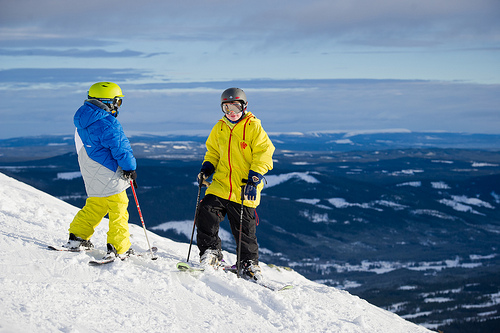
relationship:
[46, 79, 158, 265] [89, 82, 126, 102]
skiers wearing helmet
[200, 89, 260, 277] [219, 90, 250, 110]
person wearing helmet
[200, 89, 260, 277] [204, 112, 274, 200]
person wearing jacket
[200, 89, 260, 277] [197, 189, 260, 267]
person wearing pants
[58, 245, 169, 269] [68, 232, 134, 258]
skis attached to feet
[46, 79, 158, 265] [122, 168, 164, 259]
skiers holding pole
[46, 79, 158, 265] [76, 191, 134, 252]
skiers wearing pants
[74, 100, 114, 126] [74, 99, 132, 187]
hood on back of jacket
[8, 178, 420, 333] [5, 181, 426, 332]
snow on top of ground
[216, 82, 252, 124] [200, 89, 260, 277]
head of person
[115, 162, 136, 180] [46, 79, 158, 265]
hand of skiers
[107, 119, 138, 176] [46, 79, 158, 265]
arm of a skiers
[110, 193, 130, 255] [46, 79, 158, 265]
leg of a skiers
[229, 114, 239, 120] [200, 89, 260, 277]
mouth of a person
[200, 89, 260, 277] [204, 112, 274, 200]
person in jacket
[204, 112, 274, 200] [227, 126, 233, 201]
jacket has zipper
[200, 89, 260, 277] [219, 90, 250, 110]
person has helmet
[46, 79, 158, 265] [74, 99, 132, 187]
skiers wearing jacket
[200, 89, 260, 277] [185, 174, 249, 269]
person has poles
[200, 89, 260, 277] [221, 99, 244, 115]
person wearing goggles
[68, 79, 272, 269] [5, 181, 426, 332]
skiers on top of ground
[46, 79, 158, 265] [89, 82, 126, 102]
skiers has helmet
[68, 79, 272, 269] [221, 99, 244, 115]
skiers are wearing goggles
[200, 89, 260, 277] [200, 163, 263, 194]
person wearing gloves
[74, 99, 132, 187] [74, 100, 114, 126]
jacket with hood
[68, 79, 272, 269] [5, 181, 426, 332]
skiers are on top of ground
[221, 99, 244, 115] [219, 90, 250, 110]
goggles with helmet